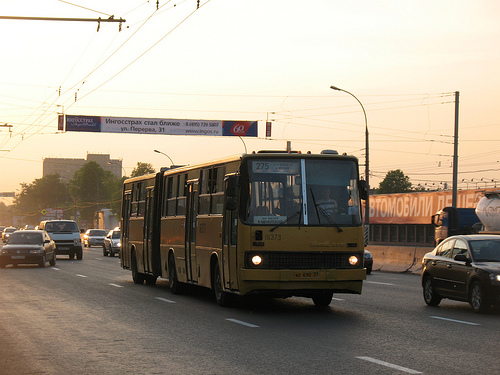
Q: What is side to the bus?
A: Car.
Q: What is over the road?
A: Sign board.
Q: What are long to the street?
A: Electrical wires.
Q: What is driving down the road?
A: Yellow bus.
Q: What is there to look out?
A: Large windows.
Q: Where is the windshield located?
A: Bus.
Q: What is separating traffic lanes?
A: Dotted lines.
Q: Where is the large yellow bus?
A: Street.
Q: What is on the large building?
A: Red and white lettering.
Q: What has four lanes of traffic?
A: Road.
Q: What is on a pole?
A: Street light.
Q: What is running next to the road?
A: Power lines.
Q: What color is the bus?
A: Yellow.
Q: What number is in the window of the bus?
A: 275.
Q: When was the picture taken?
A: Daytime.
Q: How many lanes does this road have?
A: 4.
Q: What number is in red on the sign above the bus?
A: 60.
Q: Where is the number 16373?
A: Below the right windshield of the bus.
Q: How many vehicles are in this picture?
A: 10.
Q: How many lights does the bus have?
A: 2.